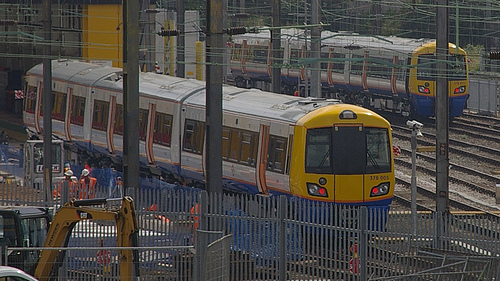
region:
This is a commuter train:
[24, 45, 416, 202]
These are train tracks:
[451, 117, 497, 203]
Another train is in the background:
[234, 20, 469, 92]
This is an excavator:
[2, 194, 153, 279]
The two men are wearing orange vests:
[56, 161, 103, 206]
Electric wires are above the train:
[136, 7, 339, 69]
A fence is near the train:
[239, 178, 439, 271]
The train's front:
[289, 104, 400, 246]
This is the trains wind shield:
[303, 123, 393, 175]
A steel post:
[201, 8, 231, 189]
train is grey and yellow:
[52, 42, 380, 213]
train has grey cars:
[46, 63, 186, 180]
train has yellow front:
[297, 105, 403, 219]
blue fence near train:
[4, 122, 371, 268]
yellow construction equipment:
[56, 206, 166, 258]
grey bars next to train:
[110, 11, 219, 198]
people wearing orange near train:
[49, 150, 199, 225]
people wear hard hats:
[53, 163, 100, 190]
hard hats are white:
[53, 165, 93, 186]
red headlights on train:
[307, 178, 387, 198]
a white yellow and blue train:
[20, 54, 415, 233]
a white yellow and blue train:
[220, 24, 476, 122]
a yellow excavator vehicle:
[5, 197, 139, 277]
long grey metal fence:
[93, 188, 498, 278]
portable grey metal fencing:
[5, 241, 187, 273]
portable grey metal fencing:
[199, 237, 234, 278]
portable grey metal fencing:
[188, 228, 225, 271]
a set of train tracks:
[388, 170, 496, 241]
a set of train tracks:
[399, 144, 497, 209]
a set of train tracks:
[396, 114, 493, 172]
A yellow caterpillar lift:
[0, 185, 143, 279]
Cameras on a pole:
[406, 119, 423, 137]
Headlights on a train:
[304, 175, 393, 201]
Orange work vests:
[80, 178, 94, 200]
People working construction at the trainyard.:
[60, 162, 97, 204]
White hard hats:
[64, 163, 96, 175]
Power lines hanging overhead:
[143, 9, 493, 69]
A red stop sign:
[347, 245, 367, 280]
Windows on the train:
[57, 88, 119, 133]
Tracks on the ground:
[465, 121, 494, 191]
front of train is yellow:
[290, 95, 408, 210]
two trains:
[231, 13, 496, 227]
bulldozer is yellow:
[18, 190, 152, 261]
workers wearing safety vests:
[53, 153, 128, 210]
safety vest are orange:
[61, 179, 115, 206]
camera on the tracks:
[390, 112, 448, 241]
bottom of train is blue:
[281, 70, 472, 128]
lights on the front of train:
[304, 174, 399, 209]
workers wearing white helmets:
[58, 159, 97, 192]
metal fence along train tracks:
[254, 185, 490, 277]